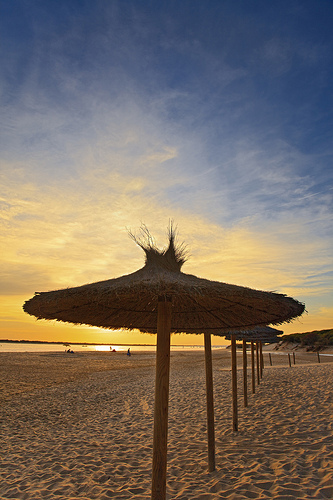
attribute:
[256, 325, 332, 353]
bluff — sandy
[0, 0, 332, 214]
sky — bright, orange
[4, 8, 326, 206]
sky — blue, daytime sky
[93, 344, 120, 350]
reflection — large, white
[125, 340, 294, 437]
poles — long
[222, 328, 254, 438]
wood pole — wooden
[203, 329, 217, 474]
pole — wooden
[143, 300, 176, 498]
poles — four, empty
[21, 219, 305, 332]
umbrella — thatched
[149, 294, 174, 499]
wood pole — wooden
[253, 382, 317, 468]
sand — beach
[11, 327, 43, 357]
water — thin, striped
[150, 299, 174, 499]
pole — wooden